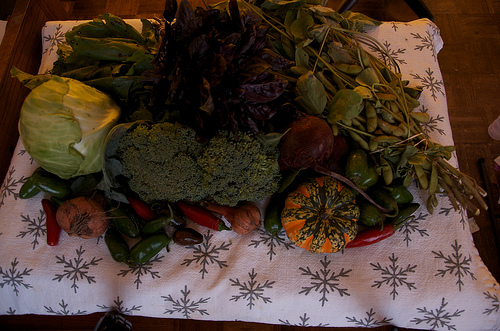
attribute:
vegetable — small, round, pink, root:
[43, 194, 127, 254]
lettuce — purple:
[145, 4, 292, 119]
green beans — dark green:
[345, 97, 441, 169]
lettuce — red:
[19, 75, 121, 182]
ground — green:
[429, 143, 444, 163]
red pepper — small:
[183, 205, 216, 232]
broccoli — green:
[115, 120, 280, 205]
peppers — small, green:
[98, 208, 168, 273]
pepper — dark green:
[124, 222, 169, 273]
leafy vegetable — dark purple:
[133, 7, 298, 133]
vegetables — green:
[41, 24, 418, 231]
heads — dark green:
[120, 135, 242, 208]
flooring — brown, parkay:
[447, 20, 494, 111]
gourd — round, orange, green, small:
[280, 176, 360, 255]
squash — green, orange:
[277, 174, 362, 254]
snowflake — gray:
[224, 261, 277, 309]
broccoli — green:
[115, 110, 280, 206]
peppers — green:
[108, 207, 178, 266]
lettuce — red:
[136, 5, 296, 137]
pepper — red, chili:
[347, 223, 393, 245]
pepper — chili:
[124, 229, 174, 271]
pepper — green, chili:
[31, 172, 71, 202]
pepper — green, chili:
[15, 167, 44, 201]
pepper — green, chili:
[100, 230, 130, 263]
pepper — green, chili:
[124, 238, 167, 269]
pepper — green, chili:
[108, 206, 141, 238]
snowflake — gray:
[14, 202, 50, 248]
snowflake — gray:
[408, 298, 466, 329]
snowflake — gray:
[431, 239, 476, 289]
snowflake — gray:
[178, 228, 235, 278]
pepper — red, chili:
[40, 193, 64, 247]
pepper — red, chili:
[123, 189, 157, 220]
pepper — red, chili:
[174, 197, 226, 229]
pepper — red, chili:
[344, 220, 399, 250]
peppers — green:
[126, 230, 169, 267]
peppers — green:
[103, 230, 131, 265]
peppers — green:
[107, 206, 141, 240]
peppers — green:
[28, 172, 70, 202]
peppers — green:
[17, 162, 48, 200]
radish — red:
[273, 108, 337, 174]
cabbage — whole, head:
[5, 63, 125, 179]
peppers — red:
[35, 199, 62, 246]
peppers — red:
[126, 191, 156, 222]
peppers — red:
[176, 200, 229, 231]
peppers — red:
[340, 220, 395, 245]